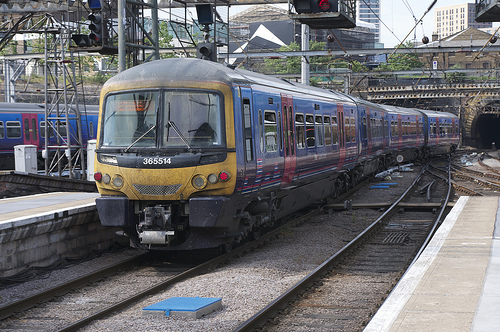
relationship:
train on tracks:
[82, 48, 471, 251] [14, 133, 457, 313]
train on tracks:
[82, 48, 471, 251] [63, 165, 454, 309]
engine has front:
[82, 58, 260, 257] [75, 43, 263, 255]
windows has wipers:
[103, 93, 235, 172] [106, 116, 219, 154]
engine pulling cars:
[97, 54, 247, 242] [54, 28, 463, 215]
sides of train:
[201, 54, 471, 187] [82, 43, 493, 237]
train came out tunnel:
[88, 57, 448, 238] [393, 78, 493, 178]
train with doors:
[73, 39, 427, 259] [222, 88, 307, 197]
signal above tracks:
[275, 2, 365, 32] [84, 165, 442, 305]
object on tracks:
[131, 287, 231, 317] [18, 233, 473, 313]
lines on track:
[163, 140, 403, 315] [179, 109, 390, 309]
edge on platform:
[405, 254, 455, 328] [382, 239, 445, 319]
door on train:
[224, 78, 302, 218] [81, 54, 470, 234]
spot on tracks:
[81, 269, 115, 314] [121, 170, 434, 303]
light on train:
[92, 158, 240, 202] [72, 31, 445, 209]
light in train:
[88, 143, 236, 211] [75, 22, 482, 256]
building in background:
[109, 3, 383, 69] [220, 18, 451, 70]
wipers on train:
[129, 109, 191, 147] [61, 34, 474, 251]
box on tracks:
[139, 287, 219, 322] [91, 235, 338, 325]